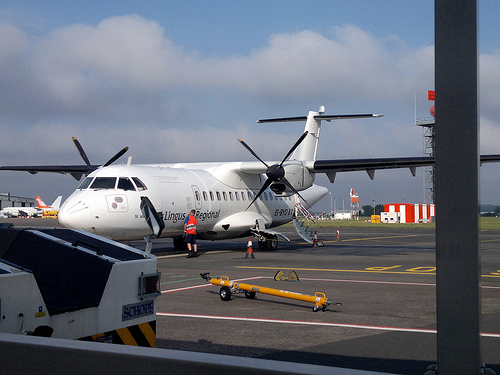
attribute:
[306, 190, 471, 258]
airfield — white, black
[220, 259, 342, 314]
pole — yellow, with wheels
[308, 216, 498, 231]
grass — green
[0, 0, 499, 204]
sky — partly cloudy, blue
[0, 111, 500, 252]
plane — white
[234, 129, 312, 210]
propeller — black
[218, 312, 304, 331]
line — white, red, solid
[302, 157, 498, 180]
wing — black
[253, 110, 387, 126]
stabilizer — black 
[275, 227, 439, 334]
runway — black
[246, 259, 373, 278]
line — yellow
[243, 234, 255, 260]
cone — orange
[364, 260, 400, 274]
p — yellow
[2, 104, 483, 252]
airplane — white